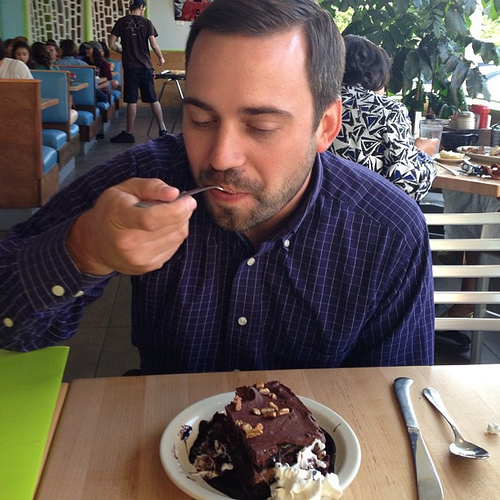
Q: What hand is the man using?
A: His right hand.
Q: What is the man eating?
A: Cake.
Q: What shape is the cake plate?
A: Round.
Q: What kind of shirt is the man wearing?
A: A plaid button-down.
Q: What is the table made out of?
A: Wood.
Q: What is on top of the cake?
A: Nuts.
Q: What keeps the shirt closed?
A: Buttons.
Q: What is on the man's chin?
A: Facial hair.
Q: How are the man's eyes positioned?
A: Closed.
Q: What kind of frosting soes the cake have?
A: Chocolate.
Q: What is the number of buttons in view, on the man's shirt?
A: 6.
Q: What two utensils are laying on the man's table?
A: A spoon and knife.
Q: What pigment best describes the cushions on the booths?
A: Blue.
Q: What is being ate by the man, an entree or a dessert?
A: Dessert.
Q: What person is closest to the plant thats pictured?
A: The woman wearing black and white.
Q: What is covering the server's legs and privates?
A: Shorts.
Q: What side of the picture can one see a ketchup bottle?
A: Right.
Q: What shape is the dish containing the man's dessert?
A: Circle.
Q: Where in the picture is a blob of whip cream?
A: On the man's dessert plate.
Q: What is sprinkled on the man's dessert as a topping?
A: Nuts.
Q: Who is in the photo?
A: A man, a lady, multiple people.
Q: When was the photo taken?
A: Lunch time.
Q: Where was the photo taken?
A: At a restaurant.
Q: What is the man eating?
A: Chocolate cake.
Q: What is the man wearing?
A: A button down shirt.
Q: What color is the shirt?
A: Navy with white check.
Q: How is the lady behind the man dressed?
A: In a black and white dress.